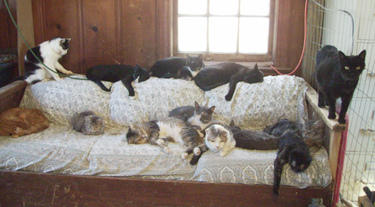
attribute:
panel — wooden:
[4, 173, 337, 205]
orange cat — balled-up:
[2, 103, 47, 135]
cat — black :
[191, 62, 262, 101]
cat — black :
[23, 36, 72, 81]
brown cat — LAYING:
[1, 107, 50, 137]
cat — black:
[308, 44, 366, 117]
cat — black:
[265, 110, 314, 199]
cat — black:
[190, 52, 266, 99]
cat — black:
[147, 46, 206, 81]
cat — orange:
[0, 108, 47, 138]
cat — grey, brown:
[262, 115, 318, 198]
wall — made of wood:
[0, 0, 325, 76]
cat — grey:
[229, 121, 279, 152]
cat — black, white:
[15, 33, 74, 84]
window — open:
[176, 1, 275, 60]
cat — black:
[316, 46, 366, 121]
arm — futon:
[303, 78, 347, 126]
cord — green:
[0, 0, 95, 83]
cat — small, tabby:
[70, 109, 106, 135]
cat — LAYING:
[80, 57, 152, 102]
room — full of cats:
[3, 3, 374, 205]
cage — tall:
[328, 98, 374, 203]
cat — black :
[263, 116, 312, 199]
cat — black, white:
[83, 62, 154, 101]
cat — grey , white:
[18, 35, 73, 84]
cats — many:
[126, 99, 235, 165]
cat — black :
[85, 64, 152, 98]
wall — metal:
[313, 1, 373, 205]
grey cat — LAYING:
[68, 110, 106, 136]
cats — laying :
[0, 38, 369, 193]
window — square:
[174, 4, 270, 55]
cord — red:
[267, 0, 315, 79]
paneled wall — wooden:
[39, 1, 174, 97]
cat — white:
[22, 36, 75, 85]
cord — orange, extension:
[265, 0, 310, 74]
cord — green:
[4, 3, 43, 71]